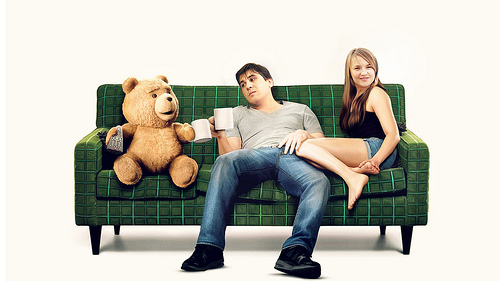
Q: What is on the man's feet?
A: Black pair of shoes.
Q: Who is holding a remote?
A: Teddy bear.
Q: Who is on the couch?
A: Two people and a teddy bear.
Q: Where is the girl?
A: On the right.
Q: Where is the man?
A: Middle.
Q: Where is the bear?
A: On left.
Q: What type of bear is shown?
A: Teddy bear.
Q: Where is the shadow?
A: Under couch.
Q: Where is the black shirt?
A: On girl.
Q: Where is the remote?
A: Bear's right hand.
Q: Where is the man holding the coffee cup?
A: Right hand.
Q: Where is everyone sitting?
A: On couch.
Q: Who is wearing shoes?
A: Man in jeans.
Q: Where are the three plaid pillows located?
A: Couch.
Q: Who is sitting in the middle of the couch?
A: A man.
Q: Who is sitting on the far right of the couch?
A: A girl.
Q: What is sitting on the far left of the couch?
A: Bear.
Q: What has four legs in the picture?
A: Couch.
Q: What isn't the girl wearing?
A: Shoes.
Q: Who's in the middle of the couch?
A: A man.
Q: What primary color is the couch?
A: Green.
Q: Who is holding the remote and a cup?
A: Bear.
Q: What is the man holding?
A: A white mug.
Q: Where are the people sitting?
A: On a green sofa.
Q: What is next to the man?
A: Ted, the bear.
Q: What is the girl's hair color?
A: Blonde.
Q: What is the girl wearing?
A: Black top and shorts.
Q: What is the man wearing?
A: Gray t-shirt and denim.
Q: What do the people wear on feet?
A: Barefoot and black boots.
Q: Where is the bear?
A: On the left.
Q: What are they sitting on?
A: A couch.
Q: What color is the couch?
A: Green.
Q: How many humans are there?
A: Two.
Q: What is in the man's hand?
A: A coffee mug.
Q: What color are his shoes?
A: Black.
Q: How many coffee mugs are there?
A: Two.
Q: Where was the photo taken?
A: In the living room.